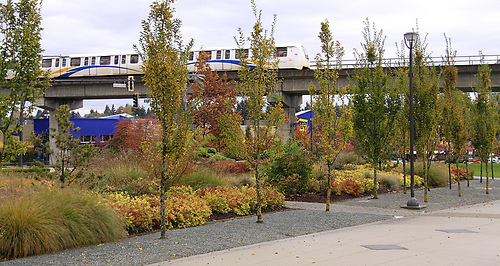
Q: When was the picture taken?
A: Daytime.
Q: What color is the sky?
A: Blue and gray.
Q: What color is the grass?
A: Green.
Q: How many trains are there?
A: One.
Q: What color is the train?
A: Yellow, blue, and white.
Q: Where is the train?
A: On the tracks.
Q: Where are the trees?
A: On the sidewalk.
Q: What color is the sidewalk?
A: Gray.